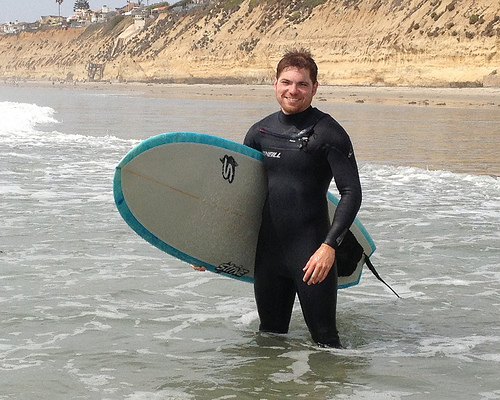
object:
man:
[243, 45, 363, 347]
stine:
[216, 259, 249, 279]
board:
[112, 131, 377, 290]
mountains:
[0, 0, 499, 89]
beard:
[277, 92, 312, 113]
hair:
[277, 50, 318, 84]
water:
[0, 86, 499, 399]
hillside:
[0, 1, 499, 87]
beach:
[0, 81, 499, 110]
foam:
[0, 102, 54, 149]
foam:
[359, 164, 498, 195]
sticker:
[219, 154, 236, 184]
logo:
[259, 150, 284, 158]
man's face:
[277, 65, 314, 113]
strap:
[365, 258, 401, 299]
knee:
[309, 323, 339, 343]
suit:
[243, 108, 362, 346]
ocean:
[1, 81, 498, 399]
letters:
[216, 263, 230, 270]